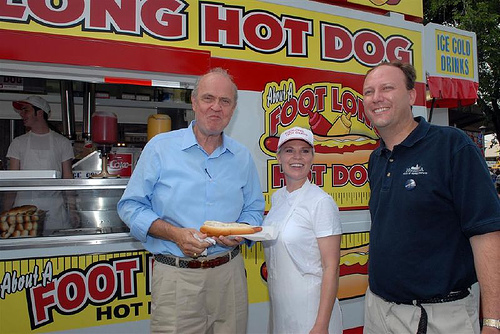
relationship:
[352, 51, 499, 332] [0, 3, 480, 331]
man near truck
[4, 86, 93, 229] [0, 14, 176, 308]
employee inside of truck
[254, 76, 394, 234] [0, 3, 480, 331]
logo of truck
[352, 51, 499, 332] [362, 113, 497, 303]
man wearing shirt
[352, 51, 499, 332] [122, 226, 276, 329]
man wearing khakis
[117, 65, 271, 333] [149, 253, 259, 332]
man wearing khakis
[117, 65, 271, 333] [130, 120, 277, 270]
man wearing shirt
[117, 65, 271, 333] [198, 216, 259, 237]
man eating hot dog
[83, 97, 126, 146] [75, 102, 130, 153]
container of ketchup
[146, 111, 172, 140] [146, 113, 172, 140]
container of container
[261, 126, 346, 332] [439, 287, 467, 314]
woman wearing belt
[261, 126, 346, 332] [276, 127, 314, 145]
woman wearing cap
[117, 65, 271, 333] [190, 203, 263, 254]
man has hotdog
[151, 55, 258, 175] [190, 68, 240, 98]
man has hair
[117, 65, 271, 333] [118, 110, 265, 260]
man wearing shirt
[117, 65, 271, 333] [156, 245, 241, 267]
man wearing belt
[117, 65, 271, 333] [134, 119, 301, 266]
man wearing shirt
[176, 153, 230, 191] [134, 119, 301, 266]
pen in shirt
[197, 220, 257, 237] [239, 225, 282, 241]
hot dog on paper wrapper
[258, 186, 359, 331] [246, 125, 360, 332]
apron on woman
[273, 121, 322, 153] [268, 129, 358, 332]
cap on woman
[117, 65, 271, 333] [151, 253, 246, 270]
man wearing belt